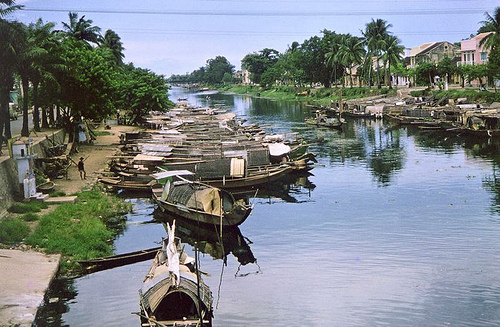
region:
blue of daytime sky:
[0, 3, 485, 73]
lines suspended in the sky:
[27, 8, 472, 38]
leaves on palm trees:
[332, 18, 404, 91]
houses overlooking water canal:
[336, 30, 494, 90]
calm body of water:
[51, 88, 497, 324]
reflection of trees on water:
[175, 87, 424, 189]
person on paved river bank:
[75, 154, 87, 184]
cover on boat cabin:
[166, 179, 231, 210]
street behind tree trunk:
[6, 105, 59, 141]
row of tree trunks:
[7, 85, 61, 141]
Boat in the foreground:
[130, 219, 214, 326]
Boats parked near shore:
[100, 97, 314, 324]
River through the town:
[32, 81, 497, 324]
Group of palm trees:
[324, 18, 409, 93]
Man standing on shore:
[78, 156, 87, 180]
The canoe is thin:
[78, 245, 161, 267]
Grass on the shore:
[1, 189, 131, 262]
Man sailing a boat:
[302, 109, 344, 130]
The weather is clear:
[1, 0, 498, 78]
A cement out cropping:
[1, 249, 60, 326]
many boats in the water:
[142, 91, 301, 325]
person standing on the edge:
[68, 142, 91, 182]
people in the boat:
[306, 100, 350, 135]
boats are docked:
[108, 118, 295, 191]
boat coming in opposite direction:
[138, 229, 221, 324]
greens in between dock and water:
[46, 183, 133, 253]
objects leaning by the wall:
[0, 129, 47, 197]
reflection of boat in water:
[222, 226, 272, 293]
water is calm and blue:
[356, 183, 497, 323]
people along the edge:
[328, 94, 362, 116]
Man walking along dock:
[76, 155, 88, 182]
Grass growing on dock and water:
[28, 185, 125, 256]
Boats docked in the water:
[118, 98, 310, 197]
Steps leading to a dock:
[30, 190, 85, 203]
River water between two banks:
[53, 75, 498, 322]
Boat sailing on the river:
[301, 105, 348, 130]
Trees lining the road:
[0, 17, 126, 131]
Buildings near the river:
[326, 31, 499, 85]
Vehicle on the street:
[6, 100, 22, 117]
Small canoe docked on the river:
[75, 240, 178, 271]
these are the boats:
[133, 84, 272, 242]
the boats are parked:
[118, 80, 275, 236]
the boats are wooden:
[155, 103, 255, 196]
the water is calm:
[346, 180, 453, 320]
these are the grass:
[56, 203, 91, 240]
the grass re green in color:
[56, 200, 104, 239]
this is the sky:
[167, 7, 217, 39]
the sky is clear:
[171, 2, 258, 46]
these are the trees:
[298, 30, 373, 65]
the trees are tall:
[305, 22, 380, 63]